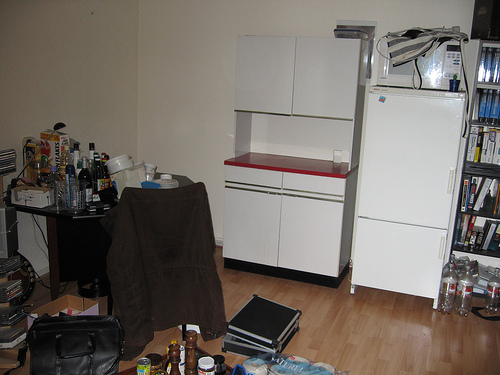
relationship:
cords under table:
[19, 210, 50, 277] [91, 207, 185, 285]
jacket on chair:
[104, 180, 226, 361] [108, 181, 187, 341]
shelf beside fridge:
[218, 98, 366, 184] [349, 85, 467, 311]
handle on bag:
[55, 328, 97, 360] [7, 314, 124, 372]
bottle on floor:
[483, 268, 498, 315] [24, 245, 499, 373]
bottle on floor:
[452, 264, 474, 316] [24, 245, 499, 373]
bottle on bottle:
[483, 268, 498, 315] [483, 268, 498, 315]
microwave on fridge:
[377, 34, 462, 90] [349, 85, 467, 311]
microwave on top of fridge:
[372, 36, 480, 92] [351, 56, 491, 349]